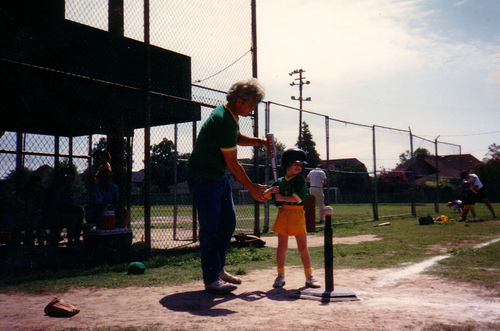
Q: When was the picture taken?
A: In the daytime.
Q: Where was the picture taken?
A: In a park.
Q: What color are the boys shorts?
A: Yellow.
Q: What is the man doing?
A: Showing the boy how to hit the ball.